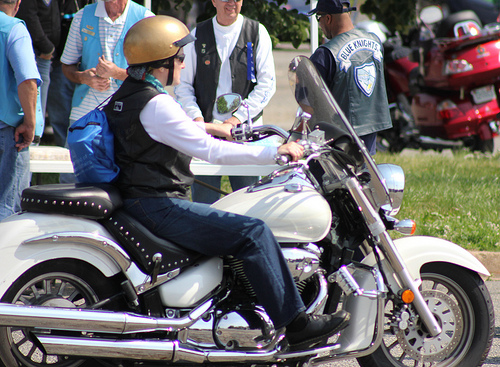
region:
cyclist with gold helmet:
[103, 5, 238, 150]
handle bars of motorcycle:
[209, 77, 381, 214]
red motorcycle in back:
[383, 2, 497, 151]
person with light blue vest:
[62, 3, 155, 142]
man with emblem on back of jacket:
[297, 0, 415, 148]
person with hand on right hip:
[5, 0, 51, 205]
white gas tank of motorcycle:
[187, 155, 340, 247]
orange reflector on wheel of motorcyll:
[373, 241, 450, 346]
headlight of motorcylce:
[359, 138, 432, 225]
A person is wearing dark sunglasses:
[31, 15, 466, 356]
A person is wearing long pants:
[10, 12, 485, 362]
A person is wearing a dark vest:
[50, 6, 455, 306]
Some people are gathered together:
[1, 2, 496, 342]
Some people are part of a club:
[0, 0, 497, 330]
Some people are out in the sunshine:
[26, 12, 491, 363]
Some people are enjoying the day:
[17, 16, 466, 366]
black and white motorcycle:
[0, 55, 495, 363]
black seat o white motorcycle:
[19, 177, 204, 271]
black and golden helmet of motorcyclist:
[124, 15, 192, 72]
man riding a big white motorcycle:
[101, 16, 351, 350]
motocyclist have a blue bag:
[69, 107, 123, 189]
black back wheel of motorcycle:
[0, 250, 130, 365]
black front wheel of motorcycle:
[354, 257, 491, 365]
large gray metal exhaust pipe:
[0, 301, 275, 355]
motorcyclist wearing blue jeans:
[107, 13, 348, 350]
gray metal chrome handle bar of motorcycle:
[227, 124, 316, 181]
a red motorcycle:
[390, 39, 492, 144]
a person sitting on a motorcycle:
[89, 52, 331, 306]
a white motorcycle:
[6, 157, 448, 364]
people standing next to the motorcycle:
[6, 3, 395, 140]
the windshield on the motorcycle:
[280, 57, 355, 123]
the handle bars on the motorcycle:
[224, 111, 321, 160]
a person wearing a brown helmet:
[120, 47, 243, 257]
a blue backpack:
[65, 110, 126, 182]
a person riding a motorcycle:
[0, 23, 444, 365]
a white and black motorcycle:
[1, 141, 498, 353]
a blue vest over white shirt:
[45, 6, 175, 129]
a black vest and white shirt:
[84, 83, 289, 227]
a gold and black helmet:
[107, 7, 202, 89]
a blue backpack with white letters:
[22, 82, 179, 214]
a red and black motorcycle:
[370, 8, 499, 162]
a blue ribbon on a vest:
[232, 30, 277, 107]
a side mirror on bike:
[207, 89, 269, 141]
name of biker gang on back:
[332, 29, 396, 131]